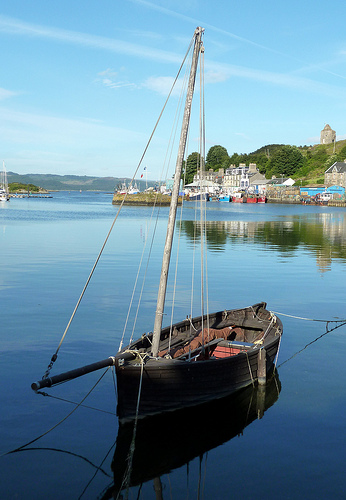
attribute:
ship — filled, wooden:
[30, 20, 282, 427]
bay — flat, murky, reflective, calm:
[0, 194, 345, 499]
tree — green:
[203, 143, 228, 170]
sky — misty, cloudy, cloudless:
[1, 1, 343, 182]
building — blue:
[300, 183, 345, 198]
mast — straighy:
[149, 26, 203, 357]